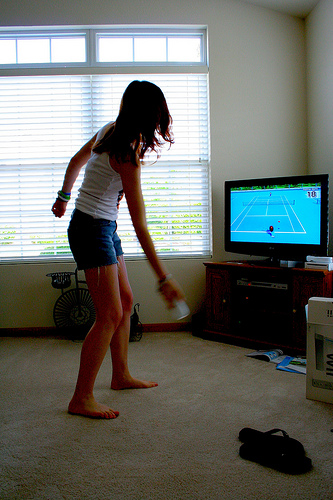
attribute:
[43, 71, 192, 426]
girl — playing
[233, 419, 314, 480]
flip flops — black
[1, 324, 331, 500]
floor — carpeted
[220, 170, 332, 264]
television — black, flat screen, large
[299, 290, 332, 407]
box — white, opened, packaging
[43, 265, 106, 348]
decoration — black, metal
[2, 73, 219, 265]
blinds — white, large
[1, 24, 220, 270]
windows — at home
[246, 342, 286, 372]
book — open, blue, white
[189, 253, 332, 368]
console — brown, wood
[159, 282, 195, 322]
handle — white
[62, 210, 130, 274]
short — blue, denim, cut off, jean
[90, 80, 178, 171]
hair — long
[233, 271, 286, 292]
dvd player — long, gray, silver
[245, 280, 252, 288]
light — red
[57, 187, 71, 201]
bracelets — on wrist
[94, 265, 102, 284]
fringe — white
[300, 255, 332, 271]
console — wii